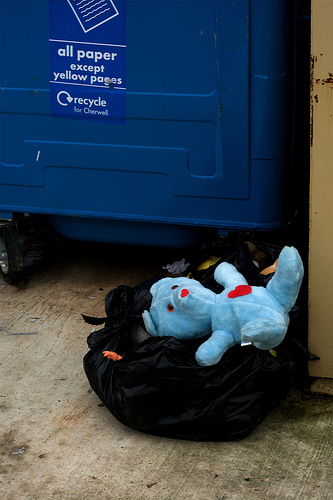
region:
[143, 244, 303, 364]
A teddy bear is on the bag.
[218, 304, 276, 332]
The teddy bear is blue.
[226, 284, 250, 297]
A heart is on the bear.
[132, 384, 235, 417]
The bag is black.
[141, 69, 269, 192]
A recycling bin is behind the bear.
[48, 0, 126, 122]
A sign is on the bin.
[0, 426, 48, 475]
The ground is dirty.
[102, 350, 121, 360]
An orange object sticks out of the bag.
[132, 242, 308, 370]
white stuffed animal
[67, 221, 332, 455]
black trash bag on the ground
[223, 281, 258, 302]
red heart on a white toy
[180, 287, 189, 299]
red heart nose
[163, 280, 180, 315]
two red and black eyes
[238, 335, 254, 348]
tag on a white stuffed animal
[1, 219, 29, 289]
wheel on a blue trash bin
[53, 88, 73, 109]
recycle sign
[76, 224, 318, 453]
bag of discarded toys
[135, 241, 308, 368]
Blue teddy bear on trash bag.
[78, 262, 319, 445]
Trash bag on the ground.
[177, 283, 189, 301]
Red heart nose on the bear.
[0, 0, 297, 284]
Blue trash can on the pavement.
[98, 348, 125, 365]
doll hand in trash bag.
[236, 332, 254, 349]
Tag on the bear.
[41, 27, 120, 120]
White lettering on the sign.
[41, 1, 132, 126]
sign on trash can.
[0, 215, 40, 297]
Wheel on the trash can.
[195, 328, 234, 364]
the blue arm of a teddy bear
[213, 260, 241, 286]
the blue arm of a teddy bear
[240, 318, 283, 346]
the blue leg of a teddy bear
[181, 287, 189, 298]
the red heart of the bear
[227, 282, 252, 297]
the red heart of the bear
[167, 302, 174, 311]
the red eye of the bear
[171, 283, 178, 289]
the red eye of the bear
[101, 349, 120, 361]
the plastic hand of the doll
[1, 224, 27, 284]
the wheel of the dumpster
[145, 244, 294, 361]
a teddy bear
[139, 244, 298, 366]
teddy bear is blue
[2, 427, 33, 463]
stains on the ground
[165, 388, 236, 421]
the plastic bag is black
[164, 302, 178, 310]
right eye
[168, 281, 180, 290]
left eye of the teddy bear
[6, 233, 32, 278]
a wheel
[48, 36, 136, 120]
a sign that is blue and white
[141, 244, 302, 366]
a sky blue plushie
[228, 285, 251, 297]
a red heart on the chest of the plushie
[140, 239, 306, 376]
blue teddy on top of black bag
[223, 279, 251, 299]
red heart on surface of blue teddy bear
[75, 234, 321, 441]
black plastic bag on ground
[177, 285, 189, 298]
red heart nose on blue teddy bear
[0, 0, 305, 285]
blue recycling dumpster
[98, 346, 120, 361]
doll hand portruding from black trash bag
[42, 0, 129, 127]
blue sticker on side of blue trash bin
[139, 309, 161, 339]
blue ear of stuffed teddy bear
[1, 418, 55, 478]
brown stain on concrete floor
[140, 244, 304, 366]
a blue teddy bear wit a heart nose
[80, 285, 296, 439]
a black bag of toys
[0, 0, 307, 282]
a blue recycling bin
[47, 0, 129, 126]
a blue sign saying what's allowed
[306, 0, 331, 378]
a brown metal wall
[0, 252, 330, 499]
stained concrete floor